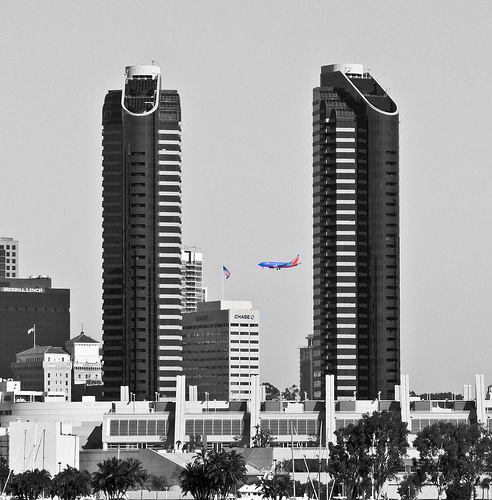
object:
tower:
[102, 65, 185, 401]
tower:
[314, 63, 401, 399]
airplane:
[258, 255, 300, 272]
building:
[182, 301, 259, 400]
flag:
[222, 266, 232, 280]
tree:
[52, 464, 93, 499]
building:
[8, 421, 79, 481]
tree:
[204, 450, 250, 499]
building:
[102, 374, 491, 453]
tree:
[255, 471, 293, 499]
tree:
[346, 409, 408, 499]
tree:
[411, 420, 492, 499]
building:
[1, 278, 71, 380]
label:
[3, 286, 45, 293]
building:
[10, 346, 72, 402]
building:
[65, 322, 103, 386]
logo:
[235, 315, 256, 320]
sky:
[1, 0, 492, 400]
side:
[183, 309, 229, 398]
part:
[196, 300, 253, 311]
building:
[0, 237, 19, 279]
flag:
[26, 326, 34, 335]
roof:
[16, 346, 69, 356]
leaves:
[222, 473, 228, 484]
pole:
[221, 266, 225, 301]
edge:
[229, 308, 260, 401]